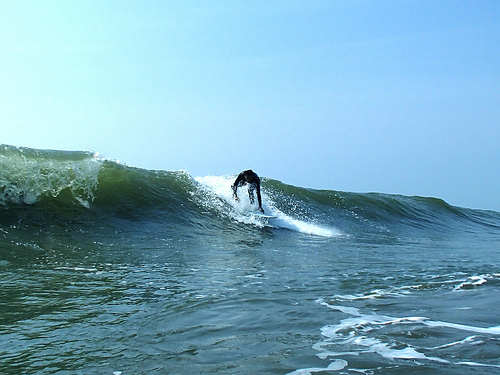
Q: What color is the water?
A: Blue and white.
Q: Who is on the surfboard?
A: The surfer.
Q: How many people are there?
A: One.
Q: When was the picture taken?
A: Daytime.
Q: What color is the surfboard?
A: White.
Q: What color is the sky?
A: Blue.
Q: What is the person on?
A: The surfboard.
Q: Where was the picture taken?
A: In the ocean.